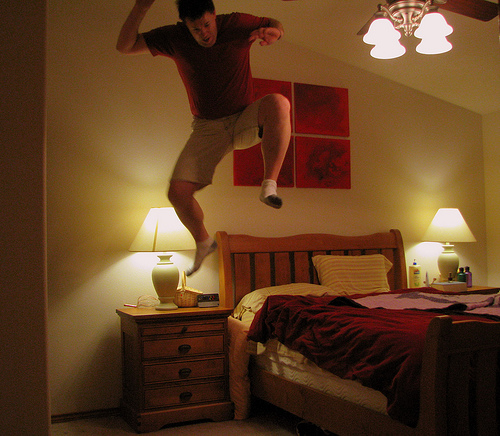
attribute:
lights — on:
[363, 12, 455, 60]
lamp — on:
[422, 205, 476, 291]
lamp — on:
[128, 204, 194, 313]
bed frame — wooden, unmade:
[208, 227, 499, 434]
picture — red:
[233, 78, 353, 192]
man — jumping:
[114, 1, 292, 277]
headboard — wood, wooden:
[210, 231, 414, 308]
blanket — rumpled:
[353, 289, 498, 316]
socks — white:
[182, 177, 283, 280]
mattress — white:
[234, 289, 500, 414]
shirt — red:
[138, 12, 273, 121]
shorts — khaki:
[167, 93, 263, 188]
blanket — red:
[246, 291, 494, 423]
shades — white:
[425, 206, 477, 247]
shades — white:
[128, 206, 198, 252]